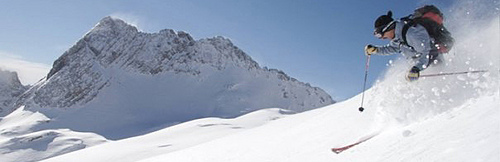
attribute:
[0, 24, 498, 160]
snow — fresh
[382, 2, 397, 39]
hat — black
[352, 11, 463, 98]
jacket — blue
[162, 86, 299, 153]
snow — fresh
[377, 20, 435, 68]
jacket — gray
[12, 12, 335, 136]
mountain — snow covered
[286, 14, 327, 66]
sky — powder blue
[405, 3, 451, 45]
backpack — orange, black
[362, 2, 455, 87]
man — skiing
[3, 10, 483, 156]
ski slope — covered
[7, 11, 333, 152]
mountain — covered